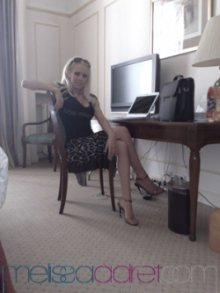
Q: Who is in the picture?
A: A blond woman.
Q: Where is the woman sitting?
A: At a desk.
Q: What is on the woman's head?
A: Sunglasses.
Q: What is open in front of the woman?
A: A laptop.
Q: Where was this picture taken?
A: A hotel room.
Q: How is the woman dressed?
A: In a skirt and heels.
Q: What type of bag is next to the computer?
A: A briefcase.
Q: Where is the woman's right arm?
A: Over the chair.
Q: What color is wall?
A: White.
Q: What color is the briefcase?
A: Black.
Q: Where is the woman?
A: Chair.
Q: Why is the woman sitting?
A: To pose.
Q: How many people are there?
A: One.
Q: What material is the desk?
A: Wood.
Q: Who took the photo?
A: Photographer.